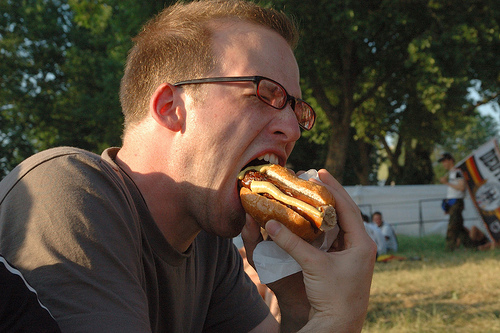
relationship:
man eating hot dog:
[44, 6, 406, 328] [254, 156, 339, 239]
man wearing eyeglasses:
[44, 6, 406, 328] [145, 54, 363, 129]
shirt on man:
[6, 118, 312, 333] [44, 6, 406, 328]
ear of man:
[146, 77, 182, 146] [44, 6, 406, 328]